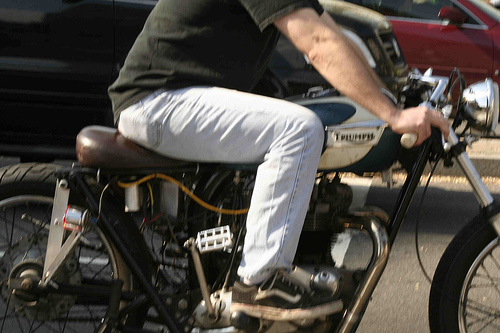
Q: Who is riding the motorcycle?
A: A man.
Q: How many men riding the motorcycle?
A: One.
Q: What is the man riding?
A: A motorcycle.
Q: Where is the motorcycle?
A: On the road.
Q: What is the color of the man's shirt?
A: Black.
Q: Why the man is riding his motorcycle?
A: To travel.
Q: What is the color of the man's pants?
A: White.